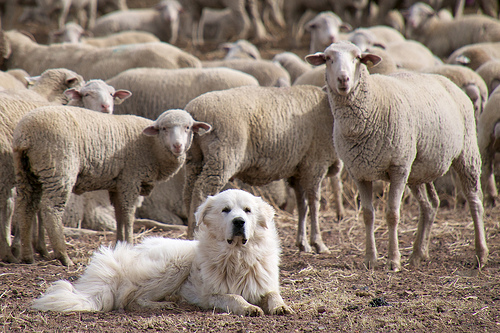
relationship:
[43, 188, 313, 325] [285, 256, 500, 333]
dog laying in grass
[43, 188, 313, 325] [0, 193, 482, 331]
dog laying on ground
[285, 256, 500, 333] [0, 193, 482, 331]
grass laying on ground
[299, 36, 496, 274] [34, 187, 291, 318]
sheep standing behind dog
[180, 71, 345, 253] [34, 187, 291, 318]
sheep standing behind dog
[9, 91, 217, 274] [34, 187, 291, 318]
sheep standing behind dog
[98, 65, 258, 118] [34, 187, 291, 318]
sheep standing behind dog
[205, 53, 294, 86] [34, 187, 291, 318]
sheep standing behind dog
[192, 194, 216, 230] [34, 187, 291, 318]
ear hanging from dog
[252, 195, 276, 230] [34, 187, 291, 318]
ear hanging from dog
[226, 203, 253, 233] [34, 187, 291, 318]
nose attached to dog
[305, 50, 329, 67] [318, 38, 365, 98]
ear sticking out of head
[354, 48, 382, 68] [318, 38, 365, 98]
ear sticking out of head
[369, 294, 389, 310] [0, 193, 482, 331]
feces laying on ground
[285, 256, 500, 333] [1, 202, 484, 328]
grass laying on dirt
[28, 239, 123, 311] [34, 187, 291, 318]
dog's tail attached to dog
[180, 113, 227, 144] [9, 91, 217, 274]
ear attached to sheep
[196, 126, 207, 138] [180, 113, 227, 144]
tag attached to ear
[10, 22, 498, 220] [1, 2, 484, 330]
herd standing inside kennel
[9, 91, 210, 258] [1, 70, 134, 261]
sheep next to sheep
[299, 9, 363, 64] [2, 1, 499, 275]
sheep next to sheep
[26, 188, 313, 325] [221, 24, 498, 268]
dog in front of sheep